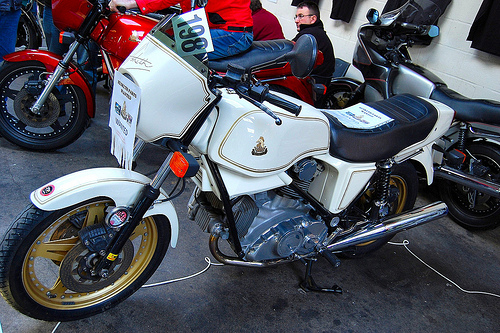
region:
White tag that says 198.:
[170, 5, 215, 57]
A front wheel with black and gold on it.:
[3, 172, 173, 322]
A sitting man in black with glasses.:
[285, 2, 335, 90]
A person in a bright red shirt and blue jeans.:
[109, 0, 255, 72]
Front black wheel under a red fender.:
[0, 53, 87, 150]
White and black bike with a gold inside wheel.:
[0, 13, 453, 323]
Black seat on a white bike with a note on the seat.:
[316, 90, 436, 160]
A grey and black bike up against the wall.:
[323, 0, 498, 230]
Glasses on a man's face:
[293, 10, 316, 21]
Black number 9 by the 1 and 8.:
[178, 23, 205, 39]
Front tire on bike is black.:
[17, 210, 165, 305]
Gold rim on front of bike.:
[37, 224, 148, 299]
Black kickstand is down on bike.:
[291, 263, 351, 306]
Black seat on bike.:
[329, 92, 414, 178]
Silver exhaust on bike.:
[331, 185, 473, 265]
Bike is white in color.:
[121, 50, 399, 232]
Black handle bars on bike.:
[168, 38, 290, 127]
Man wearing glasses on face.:
[292, 5, 307, 23]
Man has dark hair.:
[295, 0, 334, 27]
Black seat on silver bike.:
[443, 72, 497, 147]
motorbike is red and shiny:
[85, 18, 170, 76]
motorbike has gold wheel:
[34, 220, 130, 295]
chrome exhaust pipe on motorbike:
[335, 206, 437, 248]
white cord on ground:
[194, 250, 211, 280]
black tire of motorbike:
[16, 210, 21, 224]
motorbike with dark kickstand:
[286, 262, 348, 312]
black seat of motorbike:
[396, 103, 418, 140]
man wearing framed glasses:
[283, 13, 356, 83]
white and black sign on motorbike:
[174, 18, 209, 49]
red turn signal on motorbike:
[158, 140, 202, 217]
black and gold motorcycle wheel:
[1, 196, 172, 325]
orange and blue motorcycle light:
[167, 150, 201, 179]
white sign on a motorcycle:
[106, 68, 142, 170]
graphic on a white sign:
[108, 98, 134, 125]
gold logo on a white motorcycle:
[251, 135, 270, 157]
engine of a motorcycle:
[192, 158, 335, 260]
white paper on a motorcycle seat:
[319, 102, 394, 129]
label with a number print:
[169, 6, 212, 55]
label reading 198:
[172, 7, 214, 53]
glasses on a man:
[293, 13, 313, 19]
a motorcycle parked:
[0, 40, 459, 322]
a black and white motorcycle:
[12, 15, 452, 305]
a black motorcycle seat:
[318, 93, 445, 155]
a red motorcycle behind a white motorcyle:
[0, 5, 452, 319]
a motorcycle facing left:
[12, 15, 454, 320]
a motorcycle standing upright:
[5, 15, 455, 322]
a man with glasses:
[282, 1, 344, 92]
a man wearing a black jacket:
[287, 2, 336, 91]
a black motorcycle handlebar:
[216, 60, 310, 129]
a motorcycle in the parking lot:
[9, 18, 454, 315]